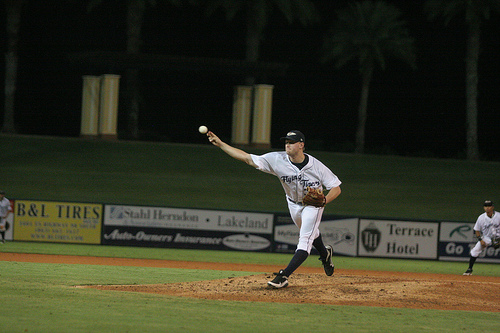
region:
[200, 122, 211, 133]
a white baseball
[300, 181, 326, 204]
a brown baseball glove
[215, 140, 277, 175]
the arm of a man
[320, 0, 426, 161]
a large green tree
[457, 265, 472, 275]
a man's tennis shoe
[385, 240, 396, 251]
a black capital letter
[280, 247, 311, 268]
a man's long black sock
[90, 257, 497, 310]
a large dirt mound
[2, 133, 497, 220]
a green grassy hill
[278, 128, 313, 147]
a black baseball cap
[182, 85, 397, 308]
a baseball player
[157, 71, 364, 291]
a pitcher throwing the ball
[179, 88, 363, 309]
a baseball player pitching the ball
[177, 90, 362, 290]
he is a baseball pitcher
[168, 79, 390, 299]
he is pitching the ball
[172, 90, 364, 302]
he threw the ball with his right hand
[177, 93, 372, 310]
he is on the pitcher's mound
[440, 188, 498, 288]
a second baseman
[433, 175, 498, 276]
a player at second base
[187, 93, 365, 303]
a man playing in a baseball game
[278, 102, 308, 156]
man has black cap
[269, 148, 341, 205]
man has white shirt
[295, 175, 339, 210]
man has brown glove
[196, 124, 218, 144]
baseball is leaving hand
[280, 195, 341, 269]
man has white pants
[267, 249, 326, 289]
man has black socks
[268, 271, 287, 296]
black and white shoes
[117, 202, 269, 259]
black and white sign behind man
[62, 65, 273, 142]
yellow and white poles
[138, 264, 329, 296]
dark brown dirt on pitcher's mound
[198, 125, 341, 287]
pitcher throwing a baseball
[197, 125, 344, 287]
man playing the pitcher position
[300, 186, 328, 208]
brown leather glove on the baseball player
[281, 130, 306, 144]
black and white hat on the pitcher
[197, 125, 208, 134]
baseball being thrown by the baseball player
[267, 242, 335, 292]
black cleats on the baseball player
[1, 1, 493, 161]
palm trees behind the baseball field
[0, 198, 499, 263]
wall at the end of the baseball field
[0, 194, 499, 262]
advertisements on the back wall of the baseball field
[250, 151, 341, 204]
black and white shirt on the pitcher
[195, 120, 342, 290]
Baseball player delivering a pitch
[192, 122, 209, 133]
White baseball thrown by baseball pitcher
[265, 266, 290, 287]
Black and white shoe of baseball pitcher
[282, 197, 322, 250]
White pants with stripe on baseball pitcher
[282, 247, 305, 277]
Black sock on baseball pitcher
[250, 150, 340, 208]
White jersey with dark lettering on baseball pitcher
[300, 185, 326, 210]
Brown glove worn by baseball pitcher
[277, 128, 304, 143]
Black hat on baseball pitcher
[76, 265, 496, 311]
Dirt pitcher's mound on baseball field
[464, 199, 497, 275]
Infielder in ready position in baseball game